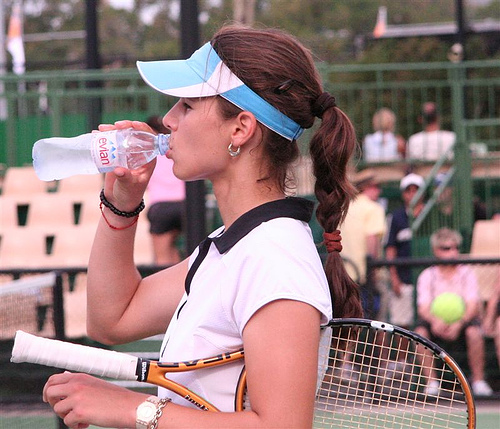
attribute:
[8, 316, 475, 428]
racket — orange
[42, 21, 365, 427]
woman — playing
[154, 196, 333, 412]
shirt — black, white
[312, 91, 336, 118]
hair band — red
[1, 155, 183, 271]
seats — empty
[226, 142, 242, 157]
earring — silver, round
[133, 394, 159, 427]
watch — silver, fancy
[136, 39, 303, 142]
visor — blue, white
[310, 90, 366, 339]
pony tail — long, brown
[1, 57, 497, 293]
fence — green, metal, black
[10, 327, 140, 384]
handle — white